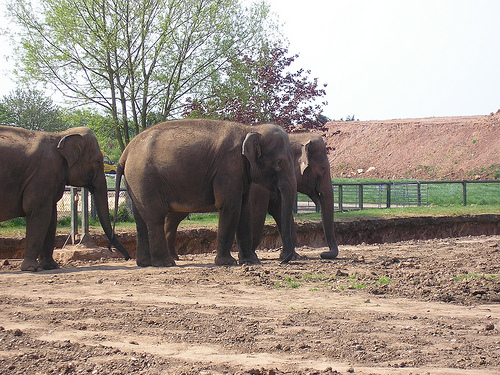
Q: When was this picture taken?
A: Daytime.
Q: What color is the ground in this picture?
A: Brown.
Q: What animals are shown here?
A: Elephants.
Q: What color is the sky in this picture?
A: White.